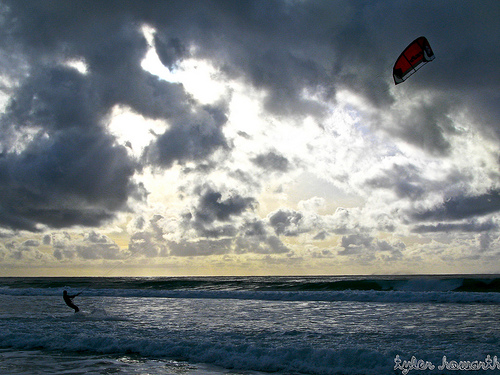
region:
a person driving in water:
[59, 283, 83, 314]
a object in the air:
[378, 36, 443, 89]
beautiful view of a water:
[18, 276, 498, 373]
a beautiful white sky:
[154, 95, 499, 272]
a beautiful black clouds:
[26, 31, 126, 224]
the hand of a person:
[71, 289, 84, 300]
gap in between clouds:
[113, 112, 165, 149]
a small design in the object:
[408, 52, 423, 65]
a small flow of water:
[22, 280, 498, 302]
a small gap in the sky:
[63, 55, 91, 80]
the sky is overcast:
[6, 13, 483, 359]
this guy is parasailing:
[38, 39, 459, 324]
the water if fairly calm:
[5, 258, 472, 372]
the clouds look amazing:
[8, 36, 389, 271]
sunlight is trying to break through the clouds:
[87, 34, 396, 244]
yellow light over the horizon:
[5, 254, 491, 317]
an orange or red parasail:
[351, 26, 462, 113]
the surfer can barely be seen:
[45, 276, 120, 324]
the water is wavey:
[14, 306, 367, 373]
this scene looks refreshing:
[36, 192, 463, 372]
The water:
[277, 317, 309, 369]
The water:
[260, 302, 317, 353]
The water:
[262, 331, 302, 371]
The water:
[289, 301, 330, 343]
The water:
[245, 295, 341, 371]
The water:
[226, 292, 298, 367]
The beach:
[266, 322, 391, 373]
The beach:
[287, 273, 330, 342]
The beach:
[300, 322, 337, 371]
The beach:
[308, 269, 367, 353]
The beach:
[254, 276, 294, 344]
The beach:
[319, 280, 349, 352]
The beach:
[281, 311, 322, 368]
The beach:
[276, 313, 306, 363]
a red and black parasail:
[387, 29, 437, 90]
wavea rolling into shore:
[246, 263, 498, 304]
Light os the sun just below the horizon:
[0, 229, 499, 271]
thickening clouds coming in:
[1, 11, 382, 271]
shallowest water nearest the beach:
[0, 336, 222, 374]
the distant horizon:
[1, 254, 497, 291]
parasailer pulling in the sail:
[53, 276, 88, 318]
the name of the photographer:
[365, 350, 498, 372]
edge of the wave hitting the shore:
[0, 315, 428, 362]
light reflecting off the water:
[93, 279, 321, 357]